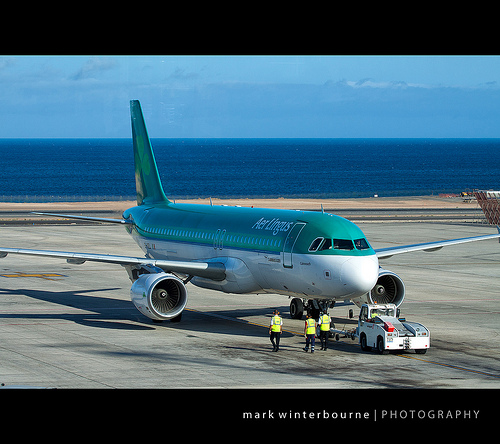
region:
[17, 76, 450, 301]
green and gray airplane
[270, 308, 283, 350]
man in yellow shirt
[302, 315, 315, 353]
man in blue jeans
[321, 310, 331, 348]
man in black jeans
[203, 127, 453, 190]
calm blue water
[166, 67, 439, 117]
cloudy blue sky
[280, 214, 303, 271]
door on green and white plane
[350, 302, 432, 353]
luggage carrier near people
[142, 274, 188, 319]
fan on airplane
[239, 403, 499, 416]
person who took the photo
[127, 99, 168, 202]
tail of a plane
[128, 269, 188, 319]
right engine of a plane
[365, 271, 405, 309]
left engine on a plane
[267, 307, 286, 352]
man in safety attire walking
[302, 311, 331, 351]
men in safety attire walking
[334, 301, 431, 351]
airplane service truck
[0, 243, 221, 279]
wing of a plane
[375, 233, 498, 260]
wing of a plane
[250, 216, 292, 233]
white lettering on a plane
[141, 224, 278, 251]
passenger windows on a plane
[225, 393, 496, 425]
Picture taken by Mark Winterbourne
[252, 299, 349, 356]
Three air traffic controllers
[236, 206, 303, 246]
Plane owned by Aer Lingus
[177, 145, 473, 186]
Water in the background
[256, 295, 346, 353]
Men wearing yellow vests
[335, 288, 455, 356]
Luggage cart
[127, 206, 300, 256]
Windows along the side of the plane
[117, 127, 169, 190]
Clover on the plane's tail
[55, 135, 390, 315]
Plane is stationary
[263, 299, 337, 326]
Men are wearing orange headphones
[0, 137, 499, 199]
water behind the airplane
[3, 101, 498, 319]
a green and white airplane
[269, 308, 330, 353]
three men walking toward the airplane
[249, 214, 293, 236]
name on side of the airplane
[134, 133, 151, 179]
shamrock on tail of the airplane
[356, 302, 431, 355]
small white vehicle in front of airplane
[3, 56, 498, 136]
the sky in background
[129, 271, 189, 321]
left motor of airplane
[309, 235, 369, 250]
cockpit windows of the airplane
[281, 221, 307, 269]
door on the airplane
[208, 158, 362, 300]
airplane is green and white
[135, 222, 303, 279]
plane has a blue stripe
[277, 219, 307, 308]
door on the airplane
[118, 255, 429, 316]
two engines on the plane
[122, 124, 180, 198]
clover on the tail of plane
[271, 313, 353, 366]
three airplane workers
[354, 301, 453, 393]
vehicle for airport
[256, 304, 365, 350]
workers wearing safety vests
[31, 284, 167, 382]
shadow on the tarmac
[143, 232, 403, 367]
airplane is on the tarmac